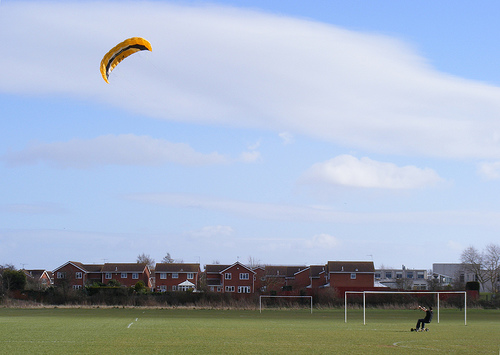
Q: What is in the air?
A: A kite.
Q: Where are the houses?
A: Behind the soccer field.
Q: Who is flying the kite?
A: The man wearing all black.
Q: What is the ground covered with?
A: Grass.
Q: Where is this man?
A: In a soccer field.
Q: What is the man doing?
A: Flying a kite.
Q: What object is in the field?
A: Soccer goals.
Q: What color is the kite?
A: Yellow.